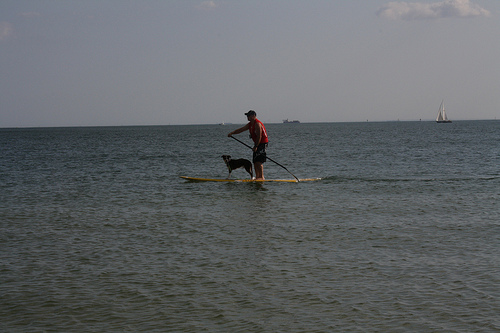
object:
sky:
[0, 0, 500, 130]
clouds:
[378, 0, 491, 24]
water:
[0, 121, 500, 333]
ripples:
[0, 121, 500, 333]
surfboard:
[182, 175, 324, 185]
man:
[225, 109, 270, 180]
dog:
[221, 154, 256, 181]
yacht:
[434, 99, 455, 124]